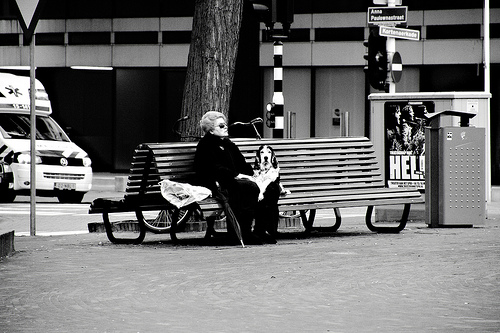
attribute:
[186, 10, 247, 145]
tree — tall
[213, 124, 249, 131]
glasses — dark colored, pair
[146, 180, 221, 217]
bag — white, plastic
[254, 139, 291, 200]
dog — sitting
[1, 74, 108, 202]
van — hospital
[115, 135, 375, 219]
bench — long, wood slat, public, wooden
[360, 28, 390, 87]
light — traffic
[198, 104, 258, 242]
woman — sitting, in black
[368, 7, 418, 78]
signs — street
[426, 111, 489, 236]
trash can — large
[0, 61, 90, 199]
ambulance — white, part, parked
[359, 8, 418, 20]
sign — street name, traffic, street, road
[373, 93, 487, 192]
service box — telephone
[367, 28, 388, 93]
traffic signal — electric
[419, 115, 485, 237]
can — trash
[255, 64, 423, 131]
window — large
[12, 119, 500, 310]
waiting area — paved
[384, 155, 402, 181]
h — letter, white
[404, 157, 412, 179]
e — letter, white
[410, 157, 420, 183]
l — letter, white